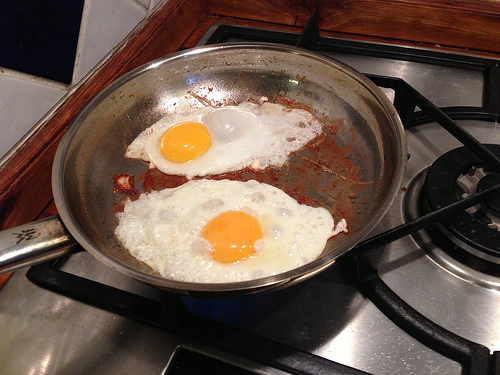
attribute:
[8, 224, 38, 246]
markings — manufacturer's 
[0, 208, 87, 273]
handle — pan  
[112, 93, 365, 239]
marks — burn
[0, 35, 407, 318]
pan — frying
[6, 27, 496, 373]
stove — silver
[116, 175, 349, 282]
egg — bottom 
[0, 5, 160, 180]
wall — tile, white, black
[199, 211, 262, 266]
egg yolks — egg , orange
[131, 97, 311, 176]
egg — fried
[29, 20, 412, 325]
pan — stainless steel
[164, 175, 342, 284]
egg — yellow yoke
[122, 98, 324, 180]
egg — top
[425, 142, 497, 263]
burner — head, gas stove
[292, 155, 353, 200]
grease — browned 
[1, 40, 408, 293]
pan — metal frying 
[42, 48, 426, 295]
pan — round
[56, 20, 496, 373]
stovetop — stove 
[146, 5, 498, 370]
stovetop — black burner covers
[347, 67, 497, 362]
burner — black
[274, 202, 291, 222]
bubbles — tiny air 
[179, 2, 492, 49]
border — wooden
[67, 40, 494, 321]
stove top — stove 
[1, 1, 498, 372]
boards — wooden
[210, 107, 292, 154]
egg whites — egg , bubbling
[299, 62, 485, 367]
grate — black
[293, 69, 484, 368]
surface — silver 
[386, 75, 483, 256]
unit — gas